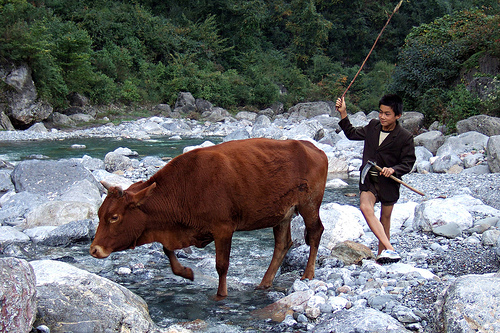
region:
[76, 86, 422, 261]
boy chasing cow through water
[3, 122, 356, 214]
water rushing over rocks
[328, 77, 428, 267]
boy wearing tennis shoes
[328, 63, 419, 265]
boy carrying pick ax and stick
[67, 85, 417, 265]
boy standing behind cow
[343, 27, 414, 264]
boy wearing white shirt with black jacket and shorts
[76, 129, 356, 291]
cow stepping in water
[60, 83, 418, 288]
boy smiling at cow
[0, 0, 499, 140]
lots of foliage on bank of water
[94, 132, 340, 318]
cow standing in a stream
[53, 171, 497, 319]
rocks are in the stream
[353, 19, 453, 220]
boy is holding a stick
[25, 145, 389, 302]
cow has is front leg up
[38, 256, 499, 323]
rocks are grey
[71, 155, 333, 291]
cow is brown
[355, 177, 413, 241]
boy is wearing shorts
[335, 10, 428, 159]
boy is holding the stick up in the air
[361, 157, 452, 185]
boy is holding a pick tool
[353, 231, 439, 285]
boy is wearing shoes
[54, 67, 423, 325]
a cow crossing water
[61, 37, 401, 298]
a brown cow crossing water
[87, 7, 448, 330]
a cow being hit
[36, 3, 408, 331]
a cow being abused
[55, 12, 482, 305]
a brown cow being hit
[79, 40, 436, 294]
a cow walking on water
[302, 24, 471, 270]
a boy holding a whip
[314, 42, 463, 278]
a boy holding an axe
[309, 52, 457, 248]
a boy standing on rocks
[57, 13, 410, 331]
a cow and boy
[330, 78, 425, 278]
person forces cow to ramble over rocks for unknown reason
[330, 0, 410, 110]
stick in hand for 'inspiring' movement; what scythe is for, in this instance, i know not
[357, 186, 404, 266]
person wears either short short or extremely highly-& tightly-rolled pants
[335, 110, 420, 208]
person's clothing all matches well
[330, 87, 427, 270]
it's sort of like he's walking a cow while he, the walker, is wearing a suit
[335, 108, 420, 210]
a _short_ [read: hot pants] suit, to be sure. & a dark brown one. w/ a cream+ brown ringer collar t-shirt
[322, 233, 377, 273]
lone dryish brown rock in a sea of white+wet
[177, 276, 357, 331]
a few tan pebbles lead into a rivulet of wetness from primary pond in back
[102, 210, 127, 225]
the cow's hide & cow's eye are the same colour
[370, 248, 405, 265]
person wears at least one white trainer/sneaker with turquoise trim+dark soles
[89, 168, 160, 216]
these are cow horns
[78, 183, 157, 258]
this is a head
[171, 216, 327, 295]
these are cow legs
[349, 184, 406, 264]
these are human legs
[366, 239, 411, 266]
this is a shoe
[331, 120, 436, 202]
this is a blazer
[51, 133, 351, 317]
this is a cow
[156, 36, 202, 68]
these are green leaves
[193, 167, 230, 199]
this is brown fur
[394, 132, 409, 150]
this is the color black